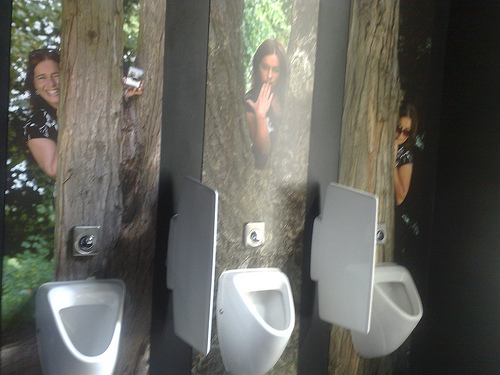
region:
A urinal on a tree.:
[18, 200, 135, 372]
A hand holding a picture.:
[92, 62, 147, 121]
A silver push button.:
[231, 214, 276, 261]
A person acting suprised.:
[208, 53, 299, 168]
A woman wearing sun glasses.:
[376, 85, 426, 220]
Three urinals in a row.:
[38, 200, 444, 374]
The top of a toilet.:
[295, 162, 390, 352]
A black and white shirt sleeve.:
[18, 102, 62, 148]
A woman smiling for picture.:
[21, 64, 73, 164]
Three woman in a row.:
[8, 31, 432, 193]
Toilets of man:
[30, 177, 431, 374]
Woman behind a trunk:
[18, 50, 146, 187]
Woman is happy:
[20, 41, 80, 112]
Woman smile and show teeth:
[20, 41, 76, 121]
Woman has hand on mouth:
[236, 35, 292, 160]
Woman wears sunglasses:
[382, 106, 417, 211]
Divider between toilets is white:
[157, 165, 227, 370]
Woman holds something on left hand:
[17, 40, 153, 167]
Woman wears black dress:
[15, 35, 88, 168]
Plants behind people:
[8, 8, 36, 315]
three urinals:
[41, 233, 457, 373]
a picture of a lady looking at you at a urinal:
[8, 42, 179, 240]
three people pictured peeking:
[14, 23, 451, 238]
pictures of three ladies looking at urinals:
[38, 23, 461, 209]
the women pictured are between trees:
[22, 16, 432, 175]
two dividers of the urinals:
[163, 175, 410, 337]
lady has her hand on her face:
[263, 48, 291, 131]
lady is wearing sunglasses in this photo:
[372, 72, 435, 211]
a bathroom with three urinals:
[24, 157, 470, 369]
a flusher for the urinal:
[234, 222, 289, 264]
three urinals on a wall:
[24, 258, 424, 373]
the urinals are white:
[30, 255, 438, 372]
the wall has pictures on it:
[4, 1, 421, 373]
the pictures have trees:
[15, 5, 415, 362]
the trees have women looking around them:
[11, 2, 422, 319]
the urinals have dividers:
[164, 171, 382, 364]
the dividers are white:
[161, 163, 389, 365]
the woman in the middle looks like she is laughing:
[243, 50, 299, 166]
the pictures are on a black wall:
[1, 0, 483, 374]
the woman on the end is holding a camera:
[117, 65, 152, 97]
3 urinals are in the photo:
[74, 240, 151, 372]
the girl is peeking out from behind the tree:
[6, 35, 79, 180]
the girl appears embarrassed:
[248, 26, 312, 164]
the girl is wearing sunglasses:
[389, 87, 426, 213]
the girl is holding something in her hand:
[115, 42, 155, 111]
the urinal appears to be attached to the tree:
[8, 0, 151, 372]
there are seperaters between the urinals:
[150, 149, 217, 367]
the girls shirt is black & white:
[18, 95, 61, 157]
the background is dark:
[416, 94, 491, 221]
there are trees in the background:
[244, 9, 291, 40]